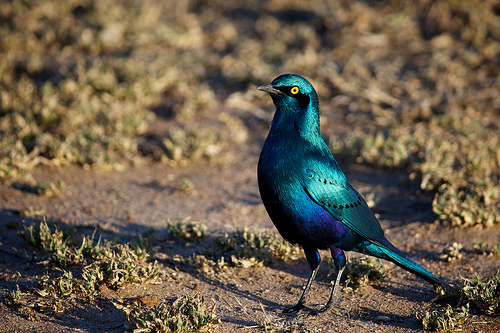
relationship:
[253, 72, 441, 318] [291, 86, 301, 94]
bird has eye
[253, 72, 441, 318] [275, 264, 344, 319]
bird has feet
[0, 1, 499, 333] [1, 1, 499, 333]
ground has grass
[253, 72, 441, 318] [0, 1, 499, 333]
bird on ground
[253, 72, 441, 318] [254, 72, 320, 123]
bird has head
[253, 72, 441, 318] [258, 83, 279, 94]
bird has beak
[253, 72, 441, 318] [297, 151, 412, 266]
bird has wing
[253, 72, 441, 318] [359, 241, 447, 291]
bird has tail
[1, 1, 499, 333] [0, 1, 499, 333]
grass on ground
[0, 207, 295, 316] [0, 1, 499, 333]
shadow on ground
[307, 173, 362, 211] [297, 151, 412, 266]
dots on wing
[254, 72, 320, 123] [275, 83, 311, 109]
head has markings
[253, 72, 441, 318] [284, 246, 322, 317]
bird has right leg